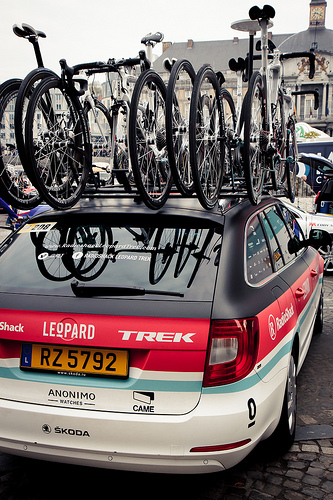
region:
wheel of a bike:
[32, 73, 95, 215]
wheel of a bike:
[9, 67, 67, 167]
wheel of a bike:
[119, 52, 179, 209]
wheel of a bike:
[161, 47, 204, 204]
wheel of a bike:
[163, 60, 243, 216]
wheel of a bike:
[221, 71, 276, 208]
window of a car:
[258, 194, 298, 264]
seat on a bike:
[244, 4, 278, 31]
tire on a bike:
[232, 80, 263, 203]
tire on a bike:
[180, 62, 210, 200]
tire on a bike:
[159, 71, 177, 175]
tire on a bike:
[126, 77, 148, 191]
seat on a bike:
[128, 24, 173, 48]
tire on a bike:
[24, 89, 42, 191]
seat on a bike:
[5, 13, 46, 42]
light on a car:
[185, 434, 260, 464]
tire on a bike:
[234, 73, 257, 191]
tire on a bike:
[181, 62, 206, 198]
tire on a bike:
[122, 69, 161, 208]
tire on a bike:
[15, 68, 72, 214]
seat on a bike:
[9, 13, 47, 46]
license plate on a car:
[18, 330, 141, 382]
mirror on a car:
[311, 219, 328, 257]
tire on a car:
[282, 352, 299, 449]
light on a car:
[187, 313, 257, 384]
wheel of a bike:
[38, 83, 97, 210]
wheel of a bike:
[2, 57, 59, 174]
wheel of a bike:
[112, 63, 175, 227]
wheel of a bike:
[164, 51, 216, 207]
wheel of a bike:
[180, 60, 219, 217]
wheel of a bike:
[238, 65, 286, 206]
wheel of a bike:
[280, 91, 310, 204]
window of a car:
[9, 215, 220, 309]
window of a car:
[229, 219, 280, 281]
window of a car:
[265, 216, 301, 266]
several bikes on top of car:
[18, 26, 309, 219]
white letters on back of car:
[4, 317, 197, 356]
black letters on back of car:
[31, 374, 171, 461]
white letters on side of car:
[259, 299, 314, 356]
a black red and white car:
[7, 203, 331, 475]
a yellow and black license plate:
[22, 338, 133, 384]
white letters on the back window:
[31, 232, 177, 289]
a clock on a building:
[303, 2, 327, 32]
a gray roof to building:
[149, 27, 331, 71]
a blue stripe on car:
[5, 265, 331, 392]